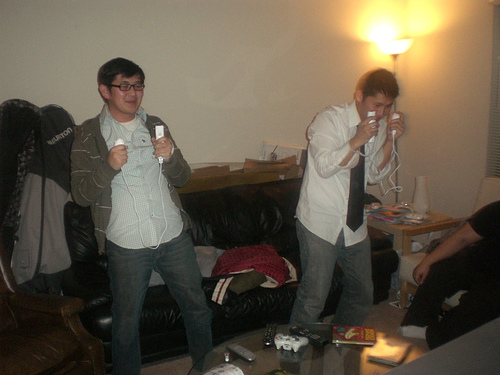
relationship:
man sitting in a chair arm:
[401, 204, 499, 351] [403, 222, 483, 274]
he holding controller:
[69, 57, 215, 374] [114, 135, 124, 145]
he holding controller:
[69, 57, 215, 374] [151, 122, 163, 163]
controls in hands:
[366, 110, 375, 144] [358, 105, 407, 147]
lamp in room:
[361, 3, 451, 90] [16, 14, 484, 303]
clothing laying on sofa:
[143, 239, 301, 311] [57, 166, 404, 370]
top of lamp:
[362, 3, 430, 38] [377, 38, 413, 57]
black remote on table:
[262, 320, 275, 347] [315, 352, 341, 368]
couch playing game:
[0, 176, 399, 375] [362, 114, 428, 181]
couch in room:
[0, 176, 399, 375] [8, 5, 488, 373]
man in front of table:
[398, 192, 498, 351] [361, 197, 463, 307]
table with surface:
[361, 197, 463, 307] [360, 189, 467, 245]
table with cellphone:
[135, 318, 425, 373] [227, 341, 254, 362]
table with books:
[135, 318, 425, 373] [334, 314, 420, 369]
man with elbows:
[293, 68, 408, 328] [298, 143, 396, 187]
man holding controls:
[293, 68, 408, 328] [360, 105, 413, 193]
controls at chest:
[91, 121, 182, 253] [330, 135, 390, 179]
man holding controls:
[297, 56, 411, 324] [91, 121, 182, 253]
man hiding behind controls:
[293, 68, 408, 328] [354, 109, 406, 165]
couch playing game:
[0, 176, 399, 375] [103, 115, 418, 186]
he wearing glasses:
[51, 51, 241, 371] [103, 72, 158, 97]